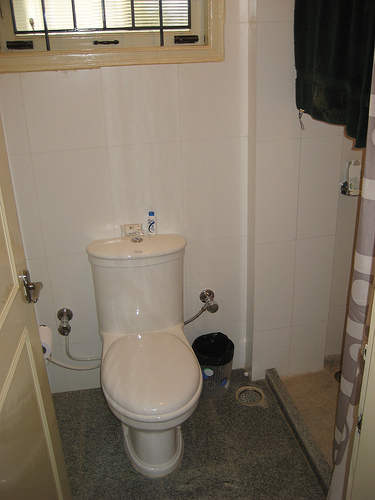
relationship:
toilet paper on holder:
[38, 322, 54, 362] [33, 314, 56, 360]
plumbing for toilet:
[54, 285, 226, 337] [33, 212, 226, 473]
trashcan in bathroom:
[190, 332, 232, 398] [4, 4, 370, 498]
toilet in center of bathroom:
[86, 233, 204, 477] [4, 4, 370, 498]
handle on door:
[16, 264, 54, 311] [2, 103, 73, 498]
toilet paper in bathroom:
[38, 325, 53, 360] [4, 4, 370, 498]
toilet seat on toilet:
[104, 334, 199, 418] [82, 218, 205, 481]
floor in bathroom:
[50, 365, 326, 498] [4, 4, 370, 498]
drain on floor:
[236, 387, 265, 408] [50, 365, 326, 498]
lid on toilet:
[130, 320, 238, 445] [83, 211, 208, 404]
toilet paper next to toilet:
[38, 322, 54, 362] [86, 233, 204, 477]